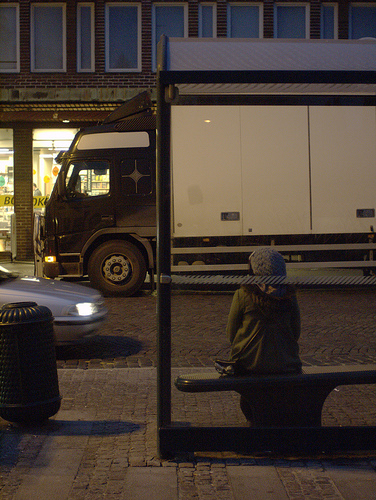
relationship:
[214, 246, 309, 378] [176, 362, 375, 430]
woman on a bench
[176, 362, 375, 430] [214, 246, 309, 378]
bench below woman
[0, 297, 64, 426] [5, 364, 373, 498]
trash can on sidewalk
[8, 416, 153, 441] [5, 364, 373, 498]
shadow on sidewalk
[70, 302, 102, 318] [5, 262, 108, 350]
headlight of car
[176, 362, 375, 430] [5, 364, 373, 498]
bench on sidewalk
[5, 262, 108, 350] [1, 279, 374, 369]
car on street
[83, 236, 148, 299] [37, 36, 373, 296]
front tire of truck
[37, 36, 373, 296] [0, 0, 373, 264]
truck by building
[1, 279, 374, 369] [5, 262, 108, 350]
street under car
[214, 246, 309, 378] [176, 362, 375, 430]
woman sitting on bench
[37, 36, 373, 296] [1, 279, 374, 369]
truck on street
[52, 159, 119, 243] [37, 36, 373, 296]
door on truck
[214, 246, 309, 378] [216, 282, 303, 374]
woman wearing coat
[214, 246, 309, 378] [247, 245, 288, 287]
woman wearing hat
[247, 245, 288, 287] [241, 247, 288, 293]
hat on head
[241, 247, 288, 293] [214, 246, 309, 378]
head of woman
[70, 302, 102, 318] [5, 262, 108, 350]
headlight on car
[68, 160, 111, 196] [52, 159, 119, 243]
window on door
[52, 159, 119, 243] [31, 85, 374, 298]
door on truck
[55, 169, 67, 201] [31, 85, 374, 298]
mirror on truck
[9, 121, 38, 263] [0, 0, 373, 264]
brick column on building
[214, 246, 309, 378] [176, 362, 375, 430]
woman on bench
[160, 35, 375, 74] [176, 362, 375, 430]
canopy top over bench